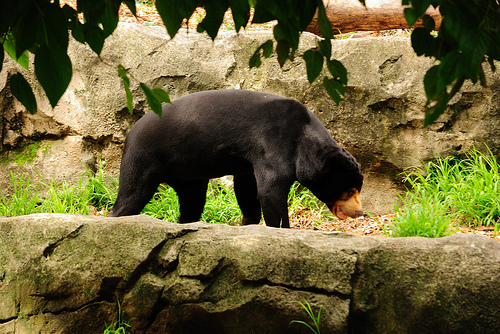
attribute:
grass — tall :
[390, 140, 498, 236]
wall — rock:
[4, 214, 497, 332]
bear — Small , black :
[108, 89, 362, 229]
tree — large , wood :
[302, 0, 498, 39]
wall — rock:
[0, 25, 500, 217]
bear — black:
[84, 71, 376, 251]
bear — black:
[117, 80, 431, 293]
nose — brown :
[324, 157, 374, 249]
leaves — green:
[397, 166, 437, 226]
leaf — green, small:
[309, 65, 362, 110]